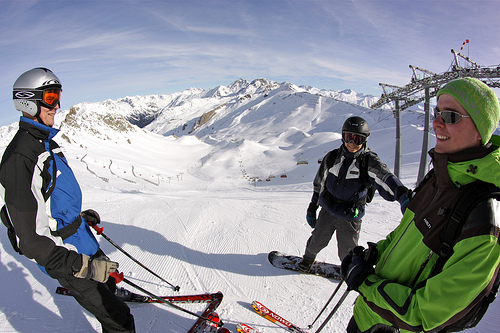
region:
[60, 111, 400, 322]
mountain is white with snow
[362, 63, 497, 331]
adult in black snow suitadult in green snow suit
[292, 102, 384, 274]
adult in black snow suit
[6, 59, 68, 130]
gray snow helmet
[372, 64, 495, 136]
metal of ski lift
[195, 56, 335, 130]
snow cover mountain side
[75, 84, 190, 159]
snow on mountain side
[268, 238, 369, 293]
black snow board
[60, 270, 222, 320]
black and red snow ski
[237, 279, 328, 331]
orange and red snow ski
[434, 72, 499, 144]
bright green toboggan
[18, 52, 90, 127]
Silver helmet on head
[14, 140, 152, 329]
Blue, white, and black jacket.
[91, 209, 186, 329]
Two ski poles in hands.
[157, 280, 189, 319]
Red and black skis on feet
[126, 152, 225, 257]
Snow covered mountain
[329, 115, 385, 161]
Black helmet on head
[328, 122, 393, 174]
Black ski goggles on face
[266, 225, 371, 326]
Person on snowboard on mountain top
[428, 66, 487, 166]
Green hat on man's head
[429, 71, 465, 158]
Glasses on man's face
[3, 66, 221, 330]
A downhill skiier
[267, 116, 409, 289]
A snow boarder wearing black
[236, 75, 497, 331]
A woman on downhill skis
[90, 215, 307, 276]
Shadow of a snowboarder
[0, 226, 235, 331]
Shadows of downhill skiiers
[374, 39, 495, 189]
A portion of a ski lift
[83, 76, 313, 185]
A mountain where people ski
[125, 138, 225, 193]
Snow on a ski hill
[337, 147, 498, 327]
A lime green and black jacket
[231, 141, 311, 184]
Ski lifts going up a hill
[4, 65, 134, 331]
a man wearing ski goggles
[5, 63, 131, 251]
a man wearing a grey helmet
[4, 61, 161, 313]
a man wearing a blue and black ski jacket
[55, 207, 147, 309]
grey gloves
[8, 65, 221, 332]
a man skiing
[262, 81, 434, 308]
a person snowboarding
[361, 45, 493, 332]
a person with a green and black ski jacket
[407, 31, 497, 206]
a person wearing sunglasses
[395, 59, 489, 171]
a person wearing a green hat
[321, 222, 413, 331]
black gloves